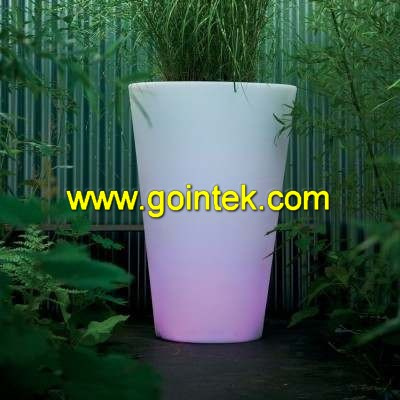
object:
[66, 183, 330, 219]
website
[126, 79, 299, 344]
planter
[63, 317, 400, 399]
ground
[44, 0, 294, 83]
foliage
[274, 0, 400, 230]
tree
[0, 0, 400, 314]
wall